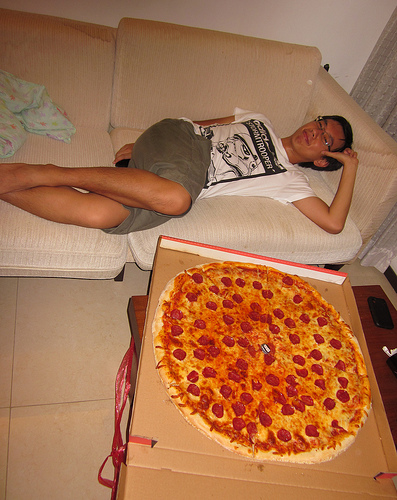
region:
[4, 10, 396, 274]
a man lying on a couch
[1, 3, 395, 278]
a couch color beige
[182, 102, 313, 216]
shirt is color white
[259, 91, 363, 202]
man has black hair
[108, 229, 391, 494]
a big pizza in a box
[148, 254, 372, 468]
a pizza of pepperoni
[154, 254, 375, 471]
sausages on a big pizza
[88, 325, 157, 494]
a string hangs from a box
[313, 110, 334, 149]
glasses on a face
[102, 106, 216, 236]
the shorts are gray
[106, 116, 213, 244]
gray shorts on a man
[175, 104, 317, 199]
a white and black shirt on a man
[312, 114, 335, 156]
glasses on a man's face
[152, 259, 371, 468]
a large pepperoni pizza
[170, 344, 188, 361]
a pepperoni on a pizza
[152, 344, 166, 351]
a piece of cheese burnt onto a crust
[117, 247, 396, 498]
the brown inside of a pizza box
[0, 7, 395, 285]
a tan couch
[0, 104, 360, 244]
a man laying on a couch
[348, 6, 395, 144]
a grey curtain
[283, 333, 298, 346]
pepperoni on the pizza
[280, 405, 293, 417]
pepperoni on the pizza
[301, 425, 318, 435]
pepperoni on the pizza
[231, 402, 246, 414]
pepperoni on the pizza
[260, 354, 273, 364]
pepperoni on the pizza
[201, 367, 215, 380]
pepperoni on the pizza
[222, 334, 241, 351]
pepperoni on the pizza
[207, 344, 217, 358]
pepperoni on the pizza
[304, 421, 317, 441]
pepperoni on the pizza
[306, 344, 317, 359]
pepperoni on the pizza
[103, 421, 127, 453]
shiny red ribbon on floor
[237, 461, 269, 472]
tiny stain on pizza box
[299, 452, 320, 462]
brown edge of pizza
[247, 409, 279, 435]
small red pepperoni slices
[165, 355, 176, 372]
brown crust on pizza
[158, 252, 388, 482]
large pepperoni pizza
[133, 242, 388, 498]
large pizza box filled with pizza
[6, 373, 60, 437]
lines on the floor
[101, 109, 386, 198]
man laying on the sofa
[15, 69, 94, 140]
green clothing on sofa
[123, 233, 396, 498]
box with a pizza in it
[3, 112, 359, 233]
man is laying on a couch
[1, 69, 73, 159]
a thin blue blanket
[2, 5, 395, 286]
a diry white couch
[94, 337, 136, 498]
a red plastic ribbon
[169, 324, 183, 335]
a pepperoni on a pizza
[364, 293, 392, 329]
phone on a table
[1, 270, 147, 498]
white tile on the floor